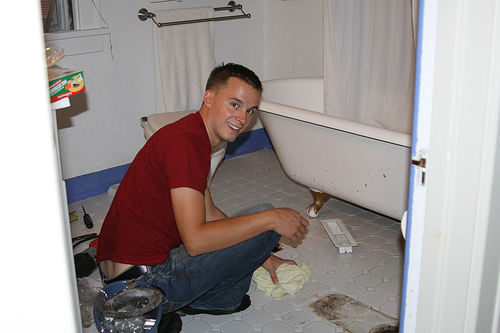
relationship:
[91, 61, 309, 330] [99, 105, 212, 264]
man in shirt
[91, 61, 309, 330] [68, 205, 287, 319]
man in jeans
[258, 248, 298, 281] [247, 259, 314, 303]
hand holding towel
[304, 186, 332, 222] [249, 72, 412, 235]
foot on tub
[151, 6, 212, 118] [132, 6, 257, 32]
towel on rod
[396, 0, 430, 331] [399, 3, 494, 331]
edge on door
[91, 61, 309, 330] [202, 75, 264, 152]
man has face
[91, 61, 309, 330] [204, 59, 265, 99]
man has hair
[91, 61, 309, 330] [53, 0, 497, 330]
man fixing bathroom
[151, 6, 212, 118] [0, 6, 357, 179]
towel on wall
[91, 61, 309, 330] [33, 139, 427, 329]
man wiping floor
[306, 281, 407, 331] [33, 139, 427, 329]
dirt on floor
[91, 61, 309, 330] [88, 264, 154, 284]
man wearing belt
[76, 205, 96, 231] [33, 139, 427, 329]
screwdriver on floor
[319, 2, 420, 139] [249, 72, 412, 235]
shower curtain on tub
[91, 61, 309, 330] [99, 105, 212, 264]
man wearing shirt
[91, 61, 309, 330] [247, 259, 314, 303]
man holding towel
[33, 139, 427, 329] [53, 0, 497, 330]
floor in bathroom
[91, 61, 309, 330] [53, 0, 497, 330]
man in bathroom